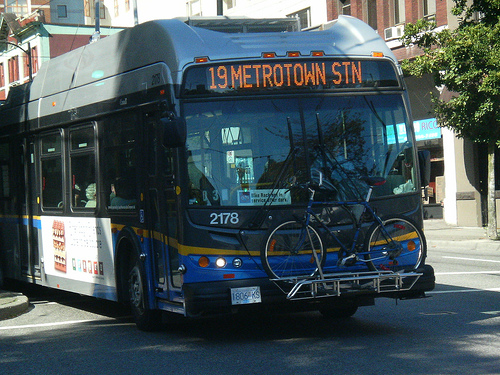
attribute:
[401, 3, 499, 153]
tree — leafy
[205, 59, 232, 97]
number — bus, 19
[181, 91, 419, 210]
window — part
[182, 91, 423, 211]
front screen — clear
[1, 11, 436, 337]
bus — window, long, pictured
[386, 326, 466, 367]
floor — part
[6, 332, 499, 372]
road — tarmac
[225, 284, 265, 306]
plate — number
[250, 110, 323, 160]
window — part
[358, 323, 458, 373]
shade — part